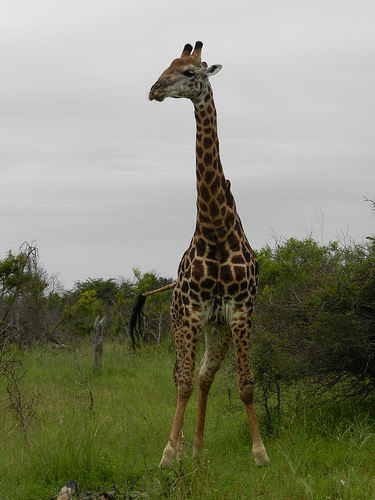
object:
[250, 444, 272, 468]
hoof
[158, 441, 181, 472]
hoof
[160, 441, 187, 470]
hoof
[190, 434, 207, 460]
hoof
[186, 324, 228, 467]
leg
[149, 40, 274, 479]
giraffe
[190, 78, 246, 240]
neck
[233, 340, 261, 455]
leg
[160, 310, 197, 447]
leg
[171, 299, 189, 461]
leg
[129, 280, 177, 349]
tail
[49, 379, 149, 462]
grass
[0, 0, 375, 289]
sky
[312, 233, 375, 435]
bush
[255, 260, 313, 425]
bush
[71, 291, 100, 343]
bush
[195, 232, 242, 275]
fur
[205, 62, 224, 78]
ear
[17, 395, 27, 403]
branch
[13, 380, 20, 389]
branch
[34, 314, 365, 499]
meadow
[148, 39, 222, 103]
head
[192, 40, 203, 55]
horn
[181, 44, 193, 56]
horn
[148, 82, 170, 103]
muzzle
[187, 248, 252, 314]
front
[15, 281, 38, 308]
bush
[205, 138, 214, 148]
spot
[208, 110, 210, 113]
spot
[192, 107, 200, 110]
spot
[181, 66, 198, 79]
eye